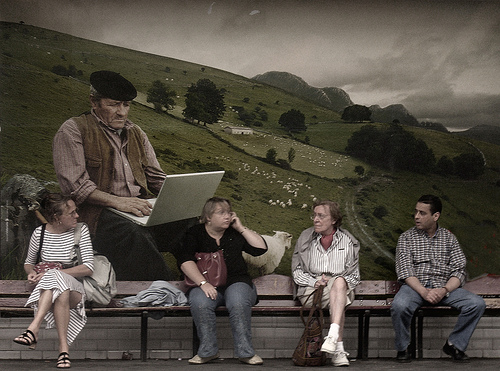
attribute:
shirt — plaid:
[378, 210, 468, 308]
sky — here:
[1, 1, 500, 133]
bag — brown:
[290, 306, 327, 368]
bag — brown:
[181, 248, 229, 293]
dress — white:
[25, 221, 96, 333]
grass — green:
[3, 16, 498, 273]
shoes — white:
[321, 333, 353, 368]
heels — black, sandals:
[13, 326, 75, 368]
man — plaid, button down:
[391, 225, 468, 289]